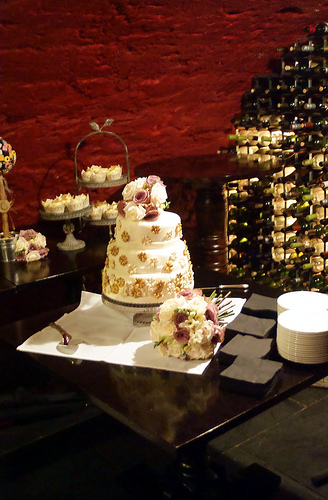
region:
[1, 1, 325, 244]
a dark red wall with an uneven surface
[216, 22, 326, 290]
many bottles on racks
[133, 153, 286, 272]
a tall, round, dark brown table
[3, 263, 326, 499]
dark brown, square, highly polished table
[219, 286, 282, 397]
four stacks of black napkins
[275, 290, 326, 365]
two stacks of white plates close together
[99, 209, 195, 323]
three-tiered wedding cake on a stand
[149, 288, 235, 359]
bouquet of pink and white flowers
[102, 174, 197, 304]
small bouquet of pink and white flowers on top of cake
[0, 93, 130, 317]
cupcakes with white frosting on table against wall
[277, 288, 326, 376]
Two stacks of white dishes.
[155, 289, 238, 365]
A flower bouquet on table.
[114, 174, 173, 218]
A bouquet of flowers as cake topper.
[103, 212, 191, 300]
A three tier cake.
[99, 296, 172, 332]
A silver cake stand on table.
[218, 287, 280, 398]
Four stacks of black napkins.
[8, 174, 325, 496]
A black table with a cake on it.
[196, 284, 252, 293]
A silver cake knife.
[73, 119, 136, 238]
A two tier metal rack.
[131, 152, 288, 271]
A round wooden table.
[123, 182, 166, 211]
flowers on the cake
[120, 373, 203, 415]
reflection on the table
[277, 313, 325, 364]
a stack of plates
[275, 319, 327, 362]
the plates are white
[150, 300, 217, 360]
flowers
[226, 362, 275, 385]
napkins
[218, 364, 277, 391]
the napkins are black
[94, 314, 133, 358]
a white cloth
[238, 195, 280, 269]
bottles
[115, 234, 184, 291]
the frosting is white on the cake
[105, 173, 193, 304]
a wedding cake with gold flowers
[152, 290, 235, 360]
a wedding flower bouquet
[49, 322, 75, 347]
a silver cake server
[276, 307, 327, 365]
a stack of plastic plates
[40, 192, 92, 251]
cupcakes on a stand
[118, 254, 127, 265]
a gold flower on a wedding cake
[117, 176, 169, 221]
pink and white flowers on a wedding cake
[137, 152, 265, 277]
a dark brown round table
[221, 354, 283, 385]
a napkin on the table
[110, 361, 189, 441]
a reflection on the table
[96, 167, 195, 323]
A cake in the foreground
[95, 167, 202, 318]
The cake is white in color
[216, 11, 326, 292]
Wine bottles in the background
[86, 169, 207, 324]
Cake has three layers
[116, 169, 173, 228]
Cake has flowers on top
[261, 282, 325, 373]
Plates in the foreground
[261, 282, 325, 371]
The plates are white in color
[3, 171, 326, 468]
Cake is on a wooden table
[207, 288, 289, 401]
Napkins are black in color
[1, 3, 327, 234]
The wall is red in color